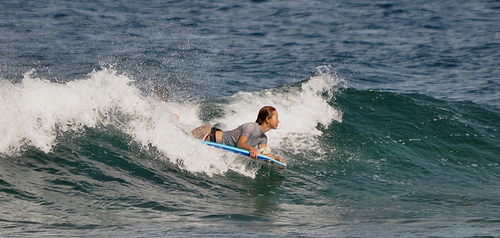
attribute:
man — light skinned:
[182, 85, 347, 170]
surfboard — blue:
[189, 124, 303, 188]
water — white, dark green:
[0, 2, 498, 235]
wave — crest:
[0, 59, 349, 190]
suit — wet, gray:
[184, 118, 274, 155]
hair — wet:
[252, 92, 282, 126]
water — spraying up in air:
[0, 41, 361, 211]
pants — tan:
[190, 115, 221, 143]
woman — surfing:
[182, 99, 293, 171]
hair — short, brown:
[253, 97, 281, 131]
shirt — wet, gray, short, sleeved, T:
[218, 118, 270, 160]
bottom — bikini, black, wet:
[190, 114, 222, 146]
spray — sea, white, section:
[0, 39, 160, 165]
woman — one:
[183, 102, 289, 166]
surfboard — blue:
[190, 136, 292, 175]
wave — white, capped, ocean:
[221, 54, 346, 104]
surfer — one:
[180, 96, 299, 167]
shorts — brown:
[189, 122, 218, 141]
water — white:
[0, 55, 353, 180]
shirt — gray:
[218, 120, 269, 150]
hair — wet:
[253, 104, 278, 125]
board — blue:
[190, 136, 291, 169]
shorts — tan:
[184, 120, 220, 140]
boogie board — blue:
[195, 137, 284, 166]